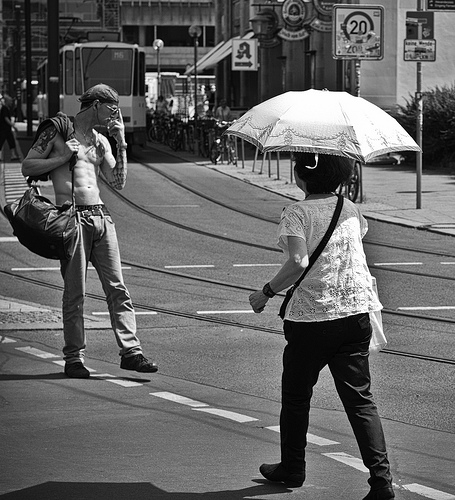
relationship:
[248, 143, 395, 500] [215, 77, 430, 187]
people carrying umbrella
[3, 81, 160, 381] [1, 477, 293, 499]
people casting shadow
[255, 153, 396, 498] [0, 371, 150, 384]
people casting shadow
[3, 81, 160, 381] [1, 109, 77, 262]
people carrying a bag